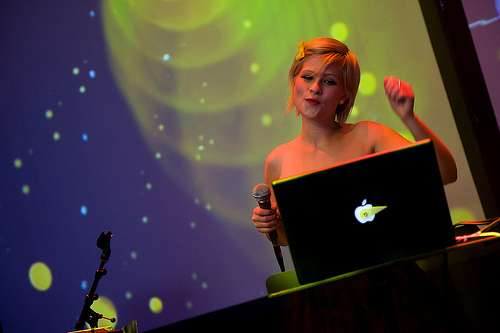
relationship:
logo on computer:
[354, 199, 388, 224] [273, 138, 457, 284]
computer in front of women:
[273, 138, 457, 284] [251, 36, 458, 246]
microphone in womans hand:
[251, 183, 285, 272] [250, 207, 277, 230]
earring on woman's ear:
[339, 98, 343, 105] [334, 91, 351, 108]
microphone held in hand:
[251, 181, 287, 271] [250, 202, 279, 234]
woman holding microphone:
[280, 43, 428, 167] [229, 177, 298, 282]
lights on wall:
[1, 2, 473, 332] [0, 0, 495, 333]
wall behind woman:
[0, 0, 495, 333] [248, 32, 462, 278]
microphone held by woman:
[251, 183, 285, 272] [248, 32, 462, 278]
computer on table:
[273, 138, 457, 284] [255, 218, 463, 330]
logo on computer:
[349, 196, 386, 229] [273, 138, 457, 284]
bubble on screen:
[73, 66, 80, 76] [0, 0, 497, 326]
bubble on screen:
[27, 257, 52, 289] [0, 0, 497, 326]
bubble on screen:
[78, 130, 88, 144] [0, 0, 497, 326]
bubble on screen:
[51, 130, 60, 141] [0, 0, 497, 326]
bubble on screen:
[78, 204, 88, 213] [0, 0, 497, 326]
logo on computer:
[354, 199, 388, 224] [288, 140, 426, 292]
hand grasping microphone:
[254, 188, 274, 248] [253, 184, 286, 272]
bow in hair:
[296, 40, 306, 60] [289, 35, 359, 75]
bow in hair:
[296, 40, 306, 60] [337, 45, 361, 127]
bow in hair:
[294, 37, 310, 61] [284, 37, 360, 127]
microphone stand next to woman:
[59, 228, 120, 328] [241, 31, 466, 244]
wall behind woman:
[7, 13, 60, 85] [255, 39, 407, 232]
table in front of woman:
[164, 252, 499, 327] [244, 26, 466, 222]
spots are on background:
[80, 206, 89, 213] [3, 2, 485, 326]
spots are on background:
[82, 136, 89, 141] [3, 2, 485, 326]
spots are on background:
[46, 111, 52, 117] [3, 2, 485, 326]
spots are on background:
[147, 184, 152, 189] [3, 2, 485, 326]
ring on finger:
[396, 77, 403, 84] [396, 78, 411, 96]